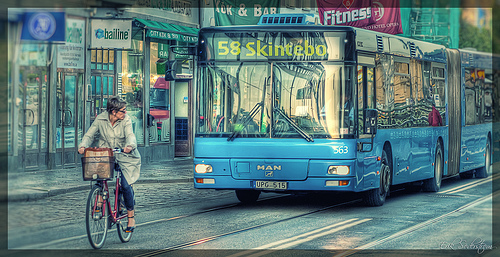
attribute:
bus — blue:
[195, 25, 496, 195]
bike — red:
[81, 174, 136, 242]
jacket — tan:
[83, 114, 142, 181]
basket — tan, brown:
[79, 153, 114, 178]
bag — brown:
[88, 150, 110, 179]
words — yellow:
[248, 41, 327, 61]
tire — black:
[371, 156, 392, 198]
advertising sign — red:
[318, 7, 402, 35]